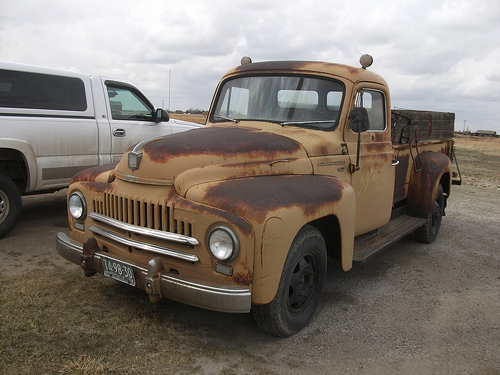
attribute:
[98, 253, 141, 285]
license plate — black and white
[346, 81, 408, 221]
door — yellow, rusty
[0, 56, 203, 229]
dirty vehicle — white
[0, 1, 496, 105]
clouds — white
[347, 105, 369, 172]
mirror — black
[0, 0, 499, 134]
sky — blue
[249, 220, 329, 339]
wheel — black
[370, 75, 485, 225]
bed — wooden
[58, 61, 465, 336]
truck — brown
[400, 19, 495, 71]
sky — blue 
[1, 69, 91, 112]
window — black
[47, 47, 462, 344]
truck — old, tan, rusty, brown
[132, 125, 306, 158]
mark — huge, rust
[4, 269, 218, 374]
grass — brown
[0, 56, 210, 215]
truck — white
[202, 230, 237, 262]
headlight — white 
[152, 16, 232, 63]
clouds — white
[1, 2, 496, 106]
sky — blue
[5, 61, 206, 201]
truck — white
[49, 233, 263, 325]
bumper — chrome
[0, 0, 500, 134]
cloud — white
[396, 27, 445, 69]
clouds — white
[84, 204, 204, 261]
grill — chrome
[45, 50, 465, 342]
pickup truck — rusty, yellow, old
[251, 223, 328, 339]
tire — black , rubber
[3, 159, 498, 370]
ground — dirt 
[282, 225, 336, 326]
tire — black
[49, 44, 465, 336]
car — brown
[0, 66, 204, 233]
car — white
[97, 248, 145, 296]
license plate — grey, white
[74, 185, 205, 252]
grill — black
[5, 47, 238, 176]
truck — white 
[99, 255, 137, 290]
license plate — black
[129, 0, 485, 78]
cloud — white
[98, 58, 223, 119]
cloud — white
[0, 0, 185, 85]
cloud — white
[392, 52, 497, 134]
cloud — white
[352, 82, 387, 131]
window — gray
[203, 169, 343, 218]
spot — rust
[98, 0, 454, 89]
sky — blue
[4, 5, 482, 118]
sky — blue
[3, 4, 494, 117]
clouds — white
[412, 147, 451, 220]
part — rusted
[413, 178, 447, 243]
wheel — rear